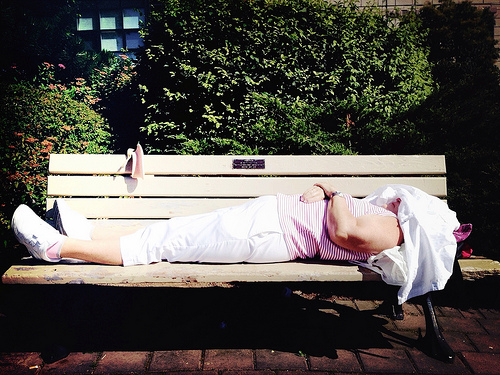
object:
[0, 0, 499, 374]
photo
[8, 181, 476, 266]
woman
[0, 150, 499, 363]
bench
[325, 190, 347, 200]
watch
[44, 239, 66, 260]
socks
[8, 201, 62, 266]
tennis shoes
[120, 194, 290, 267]
capris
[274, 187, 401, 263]
shirt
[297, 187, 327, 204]
hands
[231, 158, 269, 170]
plaque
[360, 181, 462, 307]
cloth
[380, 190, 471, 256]
head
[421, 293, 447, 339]
legs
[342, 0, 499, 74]
wall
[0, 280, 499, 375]
sidewalk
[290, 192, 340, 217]
stomach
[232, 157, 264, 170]
lettering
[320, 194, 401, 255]
arms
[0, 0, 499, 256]
bushes